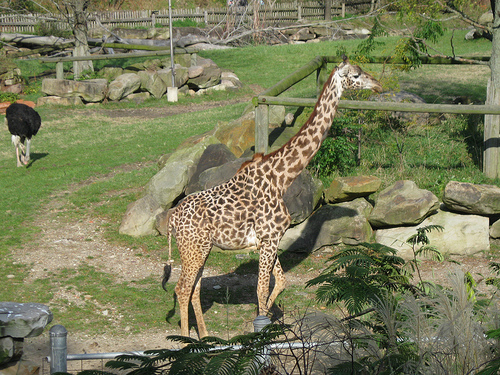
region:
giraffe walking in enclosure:
[160, 43, 388, 338]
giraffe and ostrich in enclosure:
[0, 53, 385, 338]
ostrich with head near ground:
[6, 105, 46, 169]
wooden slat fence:
[3, 2, 383, 29]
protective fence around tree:
[247, 11, 495, 181]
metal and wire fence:
[37, 315, 499, 372]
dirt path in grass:
[21, 155, 498, 314]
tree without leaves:
[1, 3, 137, 84]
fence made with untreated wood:
[253, 43, 498, 175]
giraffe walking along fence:
[48, 50, 496, 370]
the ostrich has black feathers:
[6, 95, 53, 175]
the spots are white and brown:
[197, 168, 279, 246]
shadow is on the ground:
[24, 144, 55, 177]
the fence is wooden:
[428, 85, 499, 130]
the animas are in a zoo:
[23, 58, 378, 343]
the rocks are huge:
[376, 172, 467, 225]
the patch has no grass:
[48, 223, 103, 259]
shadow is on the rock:
[303, 196, 367, 276]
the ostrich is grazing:
[3, 98, 50, 198]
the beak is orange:
[22, 158, 49, 166]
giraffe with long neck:
[155, 48, 375, 332]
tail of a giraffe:
[153, 206, 186, 301]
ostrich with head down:
[3, 97, 49, 175]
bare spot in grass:
[8, 181, 115, 290]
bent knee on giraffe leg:
[267, 248, 294, 315]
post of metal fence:
[41, 321, 72, 373]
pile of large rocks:
[44, 73, 167, 106]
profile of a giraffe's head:
[324, 52, 385, 97]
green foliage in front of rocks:
[318, 203, 420, 325]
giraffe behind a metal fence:
[158, 51, 392, 373]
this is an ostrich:
[3, 90, 50, 188]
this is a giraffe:
[165, 53, 387, 337]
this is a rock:
[367, 178, 434, 240]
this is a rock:
[269, 198, 372, 263]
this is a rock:
[448, 175, 497, 222]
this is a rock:
[111, 127, 224, 240]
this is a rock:
[187, 59, 222, 96]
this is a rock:
[108, 67, 140, 112]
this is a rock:
[41, 75, 111, 106]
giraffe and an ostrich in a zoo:
[16, 38, 383, 315]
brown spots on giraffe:
[209, 198, 244, 228]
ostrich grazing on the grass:
[12, 102, 45, 179]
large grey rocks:
[117, 166, 490, 248]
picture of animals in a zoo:
[17, 53, 420, 328]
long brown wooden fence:
[5, 9, 380, 40]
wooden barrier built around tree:
[235, 38, 487, 153]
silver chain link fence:
[38, 320, 363, 369]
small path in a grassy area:
[30, 158, 130, 293]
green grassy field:
[236, 46, 298, 76]